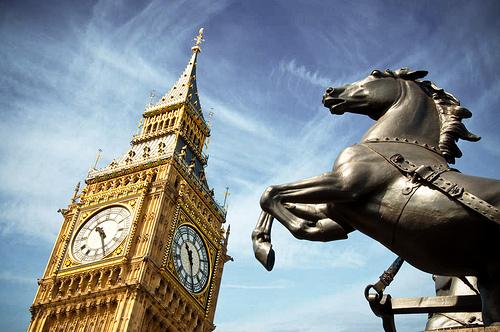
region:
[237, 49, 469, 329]
gray horse statue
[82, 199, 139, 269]
black and white clock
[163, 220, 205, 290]
black and white clock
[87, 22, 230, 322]
clock tower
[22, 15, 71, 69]
white clouds in blue sky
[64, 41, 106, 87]
white clouds in blue sky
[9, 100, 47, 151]
white clouds in blue sky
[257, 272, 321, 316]
white clouds in blue sky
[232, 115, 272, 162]
white clouds in blue sky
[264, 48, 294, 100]
white clouds in blue sky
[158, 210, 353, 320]
+two font hooves of horse statue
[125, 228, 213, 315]
white and black clock tower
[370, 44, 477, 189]
black mane of a horse statue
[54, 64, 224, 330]
gold and blue clock tower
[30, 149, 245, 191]
gold points on a building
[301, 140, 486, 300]
gray bridle for a statue horse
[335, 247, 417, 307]
rope tohold statue in place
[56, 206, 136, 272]
white clock with black hands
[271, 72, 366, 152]
mouth and nose of horse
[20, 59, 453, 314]
horse statuebeside a clock tower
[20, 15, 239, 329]
a tower with two clocks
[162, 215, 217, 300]
a white clock on the tower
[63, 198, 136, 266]
white clock on the tower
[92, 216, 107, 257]
black handles of clock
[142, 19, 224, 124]
steeple of tower is black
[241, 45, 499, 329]
a statue of a black horse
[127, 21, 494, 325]
a statue of a black horse in front a tower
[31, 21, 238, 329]
tower has intricate designs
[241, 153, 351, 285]
front legs of statue horse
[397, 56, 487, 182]
mane of statue horse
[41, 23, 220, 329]
Big Ben clock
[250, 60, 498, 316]
Bronze horse rising toward sky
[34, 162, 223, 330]
Clock is gold trimmed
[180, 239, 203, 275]
Clock face is beige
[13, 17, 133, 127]
Sky is blue with white wispy clouds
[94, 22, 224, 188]
Clock tower is white gold looking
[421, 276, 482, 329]
Horse on the other side of the first horse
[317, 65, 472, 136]
Horse looks angry.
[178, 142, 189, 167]
Four tips on the clock on each side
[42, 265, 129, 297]
Seven very small arches underneath the clock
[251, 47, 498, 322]
a beautiful horse statue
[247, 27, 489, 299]
the horse is rearing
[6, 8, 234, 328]
a huge clock tower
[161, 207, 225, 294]
the clock reads. 25 past 10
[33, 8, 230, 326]
the tower is extremely ornate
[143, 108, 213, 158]
arched windows surround the top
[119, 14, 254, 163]
the tower is very pointed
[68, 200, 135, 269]
this clock has a white face with brown trim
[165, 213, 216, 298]
this clock is white faced with black numbers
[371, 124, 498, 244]
the horse has heavy straps on him